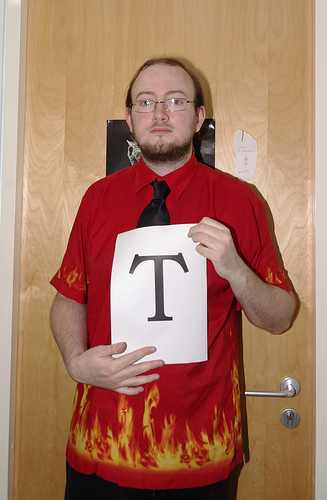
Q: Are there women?
A: No, there are no women.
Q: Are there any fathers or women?
A: No, there are no women or fathers.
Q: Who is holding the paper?
A: The man is holding the paper.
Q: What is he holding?
A: The man is holding the paper.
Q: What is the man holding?
A: The man is holding the paper.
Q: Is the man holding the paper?
A: Yes, the man is holding the paper.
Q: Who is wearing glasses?
A: The man is wearing glasses.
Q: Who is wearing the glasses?
A: The man is wearing glasses.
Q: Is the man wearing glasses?
A: Yes, the man is wearing glasses.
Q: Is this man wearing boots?
A: No, the man is wearing glasses.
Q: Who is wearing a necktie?
A: The man is wearing a necktie.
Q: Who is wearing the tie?
A: The man is wearing a necktie.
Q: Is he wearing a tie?
A: Yes, the man is wearing a tie.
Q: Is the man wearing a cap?
A: No, the man is wearing a tie.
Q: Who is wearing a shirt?
A: The man is wearing a shirt.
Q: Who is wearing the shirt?
A: The man is wearing a shirt.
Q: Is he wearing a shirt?
A: Yes, the man is wearing a shirt.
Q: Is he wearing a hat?
A: No, the man is wearing a shirt.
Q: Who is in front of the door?
A: The man is in front of the door.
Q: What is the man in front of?
A: The man is in front of the door.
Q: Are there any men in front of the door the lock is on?
A: Yes, there is a man in front of the door.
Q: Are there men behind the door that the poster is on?
A: No, the man is in front of the door.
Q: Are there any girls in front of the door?
A: No, there is a man in front of the door.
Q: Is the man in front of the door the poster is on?
A: Yes, the man is in front of the door.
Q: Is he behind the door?
A: No, the man is in front of the door.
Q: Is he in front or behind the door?
A: The man is in front of the door.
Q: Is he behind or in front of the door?
A: The man is in front of the door.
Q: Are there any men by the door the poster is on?
A: Yes, there is a man by the door.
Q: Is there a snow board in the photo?
A: No, there are no snowboards.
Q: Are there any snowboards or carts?
A: No, there are no snowboards or carts.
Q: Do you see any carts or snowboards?
A: No, there are no snowboards or carts.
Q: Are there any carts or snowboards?
A: No, there are no snowboards or carts.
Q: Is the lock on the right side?
A: Yes, the lock is on the right of the image.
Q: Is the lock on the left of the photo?
A: No, the lock is on the right of the image.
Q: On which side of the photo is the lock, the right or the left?
A: The lock is on the right of the image.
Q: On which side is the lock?
A: The lock is on the right of the image.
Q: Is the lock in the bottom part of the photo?
A: Yes, the lock is in the bottom of the image.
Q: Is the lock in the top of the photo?
A: No, the lock is in the bottom of the image.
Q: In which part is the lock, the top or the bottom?
A: The lock is in the bottom of the image.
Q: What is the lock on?
A: The lock is on the door.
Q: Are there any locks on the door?
A: Yes, there is a lock on the door.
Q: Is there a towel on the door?
A: No, there is a lock on the door.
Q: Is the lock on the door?
A: Yes, the lock is on the door.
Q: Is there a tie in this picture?
A: Yes, there is a tie.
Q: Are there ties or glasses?
A: Yes, there is a tie.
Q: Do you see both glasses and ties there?
A: Yes, there are both a tie and glasses.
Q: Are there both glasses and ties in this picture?
A: Yes, there are both a tie and glasses.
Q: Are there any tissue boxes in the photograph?
A: No, there are no tissue boxes.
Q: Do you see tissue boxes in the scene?
A: No, there are no tissue boxes.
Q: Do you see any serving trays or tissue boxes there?
A: No, there are no tissue boxes or serving trays.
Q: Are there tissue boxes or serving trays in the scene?
A: No, there are no tissue boxes or serving trays.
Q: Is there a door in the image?
A: Yes, there is a door.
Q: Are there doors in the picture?
A: Yes, there is a door.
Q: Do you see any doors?
A: Yes, there is a door.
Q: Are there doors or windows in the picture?
A: Yes, there is a door.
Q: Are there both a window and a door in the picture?
A: No, there is a door but no windows.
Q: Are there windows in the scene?
A: No, there are no windows.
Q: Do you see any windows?
A: No, there are no windows.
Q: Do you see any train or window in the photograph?
A: No, there are no windows or trains.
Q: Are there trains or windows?
A: No, there are no windows or trains.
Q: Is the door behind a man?
A: Yes, the door is behind a man.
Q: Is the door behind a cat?
A: No, the door is behind a man.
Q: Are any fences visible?
A: No, there are no fences.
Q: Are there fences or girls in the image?
A: No, there are no fences or girls.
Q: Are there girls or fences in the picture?
A: No, there are no fences or girls.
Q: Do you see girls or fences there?
A: No, there are no fences or girls.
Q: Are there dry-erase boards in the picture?
A: No, there are no dry-erase boards.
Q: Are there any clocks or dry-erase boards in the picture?
A: No, there are no dry-erase boards or clocks.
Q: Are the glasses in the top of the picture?
A: Yes, the glasses are in the top of the image.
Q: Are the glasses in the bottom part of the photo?
A: No, the glasses are in the top of the image.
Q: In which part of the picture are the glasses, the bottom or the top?
A: The glasses are in the top of the image.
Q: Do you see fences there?
A: No, there are no fences.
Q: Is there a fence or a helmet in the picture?
A: No, there are no fences or helmets.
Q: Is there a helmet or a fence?
A: No, there are no fences or helmets.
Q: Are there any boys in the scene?
A: No, there are no boys.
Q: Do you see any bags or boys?
A: No, there are no boys or bags.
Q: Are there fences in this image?
A: No, there are no fences.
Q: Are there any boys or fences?
A: No, there are no fences or boys.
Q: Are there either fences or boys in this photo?
A: No, there are no fences or boys.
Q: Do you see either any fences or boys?
A: No, there are no fences or boys.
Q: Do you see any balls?
A: No, there are no balls.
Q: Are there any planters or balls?
A: No, there are no balls or planters.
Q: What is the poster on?
A: The poster is on the door.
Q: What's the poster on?
A: The poster is on the door.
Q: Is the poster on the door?
A: Yes, the poster is on the door.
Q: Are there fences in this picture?
A: No, there are no fences.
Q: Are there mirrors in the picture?
A: No, there are no mirrors.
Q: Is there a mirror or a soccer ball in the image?
A: No, there are no mirrors or soccer balls.